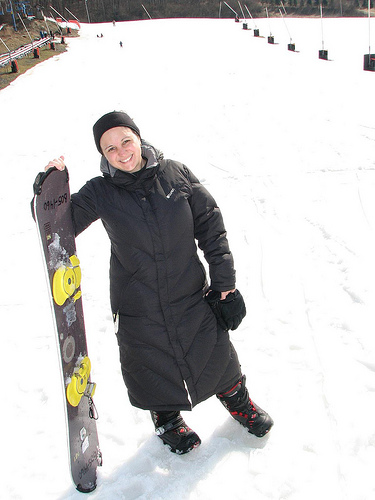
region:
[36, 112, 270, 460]
person wearing full lenght black coat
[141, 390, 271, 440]
black and red boots of person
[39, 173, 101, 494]
gray and yellow snowboard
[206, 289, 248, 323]
black glove of woman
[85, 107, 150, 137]
black knit cap of woman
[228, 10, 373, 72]
black markers along mountain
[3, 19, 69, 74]
grass along right side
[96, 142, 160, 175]
gray collar of coat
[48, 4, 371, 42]
white poles sticking out of snow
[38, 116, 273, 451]
person posing for photo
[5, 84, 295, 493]
a woman standing standing in the snow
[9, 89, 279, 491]
a snowboarder standing in the snow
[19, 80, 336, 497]
a woman holding a snowboard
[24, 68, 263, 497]
a snowboard standing in the snow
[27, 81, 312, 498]
a woman wearing jacket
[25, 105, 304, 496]
a woman wearing a black jacket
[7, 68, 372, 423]
a woman outside in the snow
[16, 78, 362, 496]
a snowboarder in the snow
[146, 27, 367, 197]
a snow covered ground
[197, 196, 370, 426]
ground covered in snow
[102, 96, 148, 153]
woman has black cap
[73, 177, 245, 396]
woman has long black coat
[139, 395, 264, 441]
black and red boots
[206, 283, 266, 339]
woman has black gloves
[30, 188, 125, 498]
woman is holding snowboard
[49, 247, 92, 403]
yellow footholds on snowboard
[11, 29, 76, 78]
red barriers on hill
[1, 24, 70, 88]
brown ground next to snow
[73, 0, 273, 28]
trees are in background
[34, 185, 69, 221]
number printed on snowboard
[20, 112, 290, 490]
person standing on snow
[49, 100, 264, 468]
person wearing long black jacket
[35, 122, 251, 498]
person holding snowboard on snow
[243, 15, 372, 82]
barriers on the snow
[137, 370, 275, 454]
black and red boots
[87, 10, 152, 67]
people in the distance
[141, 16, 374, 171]
a lot of white snow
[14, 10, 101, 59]
white poles along snow course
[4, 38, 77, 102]
red barrels on ground next to snow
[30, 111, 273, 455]
Woman wearing black coat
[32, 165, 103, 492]
Black and yellow snowboard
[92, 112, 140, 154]
Black hat on a woman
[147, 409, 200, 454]
Black boot with red accents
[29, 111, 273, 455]
Woman holding snowboard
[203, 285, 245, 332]
Black gloves for snow boarding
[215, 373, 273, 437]
Black snowboarding boots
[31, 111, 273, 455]
Woman standing next to snowboard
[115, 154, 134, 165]
Smile on woman's face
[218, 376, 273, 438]
Black boot with red accents